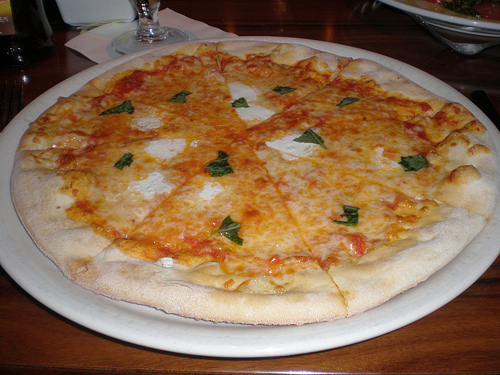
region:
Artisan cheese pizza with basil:
[10, 35, 499, 322]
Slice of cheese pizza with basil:
[78, 137, 349, 324]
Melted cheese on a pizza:
[138, 116, 205, 189]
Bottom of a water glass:
[109, 0, 196, 56]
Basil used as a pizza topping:
[204, 211, 258, 251]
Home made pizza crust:
[71, 242, 346, 329]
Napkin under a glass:
[56, 6, 239, 63]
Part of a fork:
[410, 9, 499, 56]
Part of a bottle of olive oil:
[0, 0, 66, 74]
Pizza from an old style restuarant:
[1, 33, 499, 345]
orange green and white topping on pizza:
[204, 58, 274, 121]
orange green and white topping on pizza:
[132, 80, 202, 144]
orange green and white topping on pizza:
[44, 120, 168, 203]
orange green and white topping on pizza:
[65, 148, 170, 229]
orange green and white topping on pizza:
[149, 178, 251, 265]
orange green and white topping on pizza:
[238, 146, 345, 240]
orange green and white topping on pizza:
[311, 190, 393, 275]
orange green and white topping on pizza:
[270, 111, 341, 168]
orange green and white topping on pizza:
[371, 143, 476, 220]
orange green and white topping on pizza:
[341, 67, 437, 139]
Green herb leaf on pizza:
[213, 213, 243, 251]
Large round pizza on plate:
[17, 43, 499, 329]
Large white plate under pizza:
[5, 35, 498, 357]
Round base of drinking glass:
[104, 29, 206, 57]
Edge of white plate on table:
[387, 4, 499, 36]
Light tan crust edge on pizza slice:
[59, 252, 354, 326]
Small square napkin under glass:
[57, 5, 222, 62]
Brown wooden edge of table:
[4, 303, 491, 374]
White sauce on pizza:
[140, 135, 196, 163]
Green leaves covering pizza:
[100, 74, 431, 239]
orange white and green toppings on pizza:
[55, 191, 109, 233]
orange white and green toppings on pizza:
[122, 213, 193, 287]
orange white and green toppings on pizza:
[203, 197, 266, 306]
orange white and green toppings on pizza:
[254, 201, 341, 292]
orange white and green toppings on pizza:
[323, 204, 379, 262]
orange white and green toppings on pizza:
[154, 134, 230, 185]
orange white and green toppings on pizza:
[373, 131, 432, 191]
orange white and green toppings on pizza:
[313, 83, 366, 125]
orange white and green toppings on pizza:
[209, 86, 293, 146]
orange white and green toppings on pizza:
[145, 79, 214, 138]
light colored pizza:
[16, 38, 498, 348]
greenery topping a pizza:
[203, 148, 258, 250]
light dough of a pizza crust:
[108, 236, 340, 331]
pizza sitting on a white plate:
[12, 28, 494, 355]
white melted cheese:
[228, 86, 323, 166]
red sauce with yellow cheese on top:
[97, 75, 412, 267]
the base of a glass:
[97, 0, 189, 65]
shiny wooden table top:
[224, 3, 411, 60]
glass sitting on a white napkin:
[63, 0, 215, 80]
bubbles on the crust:
[433, 95, 491, 190]